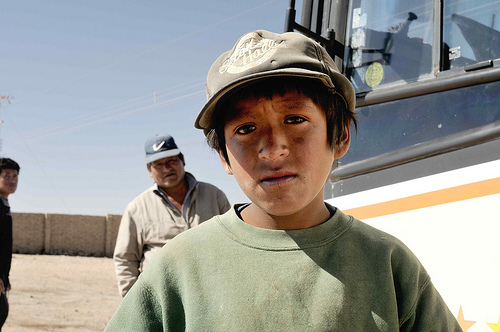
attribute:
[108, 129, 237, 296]
man — wondering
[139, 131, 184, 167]
hat — dark blue, blue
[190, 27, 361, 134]
cap — gray, black, young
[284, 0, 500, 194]
bus — large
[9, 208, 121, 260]
fence — brick, stone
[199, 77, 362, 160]
hair — uneven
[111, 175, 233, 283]
shirt — open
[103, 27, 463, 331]
boy — mexican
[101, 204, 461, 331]
sweater — green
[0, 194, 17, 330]
clothing — dark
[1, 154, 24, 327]
man — young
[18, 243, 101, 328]
area — desert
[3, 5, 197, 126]
sky — blue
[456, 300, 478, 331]
star — orange, yellow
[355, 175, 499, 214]
line — orange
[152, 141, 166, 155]
nike — white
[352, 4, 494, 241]
bus — white, black, orange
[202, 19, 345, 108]
hat — dirty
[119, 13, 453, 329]
boy — young